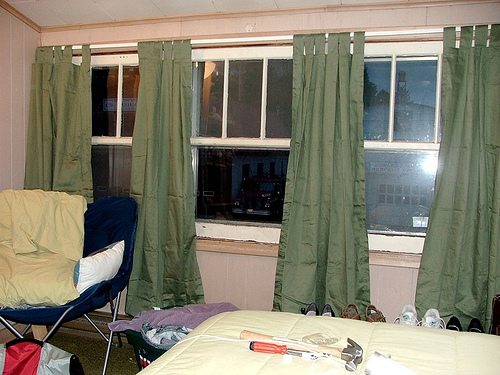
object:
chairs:
[0, 197, 139, 375]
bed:
[133, 310, 499, 375]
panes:
[92, 55, 442, 233]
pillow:
[0, 188, 87, 309]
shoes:
[301, 302, 336, 318]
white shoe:
[420, 304, 442, 328]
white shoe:
[393, 302, 418, 325]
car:
[231, 174, 286, 218]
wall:
[230, 161, 289, 174]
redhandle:
[250, 341, 287, 355]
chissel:
[248, 341, 309, 358]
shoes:
[392, 304, 445, 329]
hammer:
[238, 328, 363, 372]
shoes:
[340, 303, 387, 322]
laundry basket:
[124, 329, 167, 371]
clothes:
[107, 302, 241, 350]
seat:
[0, 186, 137, 375]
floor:
[70, 341, 133, 375]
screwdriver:
[249, 341, 310, 355]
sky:
[365, 59, 442, 110]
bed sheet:
[407, 332, 452, 359]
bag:
[1, 337, 87, 375]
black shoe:
[467, 318, 485, 333]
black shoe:
[446, 315, 462, 331]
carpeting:
[5, 331, 144, 373]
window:
[191, 59, 223, 141]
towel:
[119, 305, 230, 341]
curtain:
[22, 43, 94, 203]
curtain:
[124, 38, 205, 316]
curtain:
[271, 31, 370, 316]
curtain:
[415, 24, 500, 330]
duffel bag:
[0, 339, 88, 375]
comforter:
[203, 330, 435, 373]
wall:
[0, 7, 40, 344]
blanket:
[0, 188, 88, 308]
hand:
[249, 341, 287, 356]